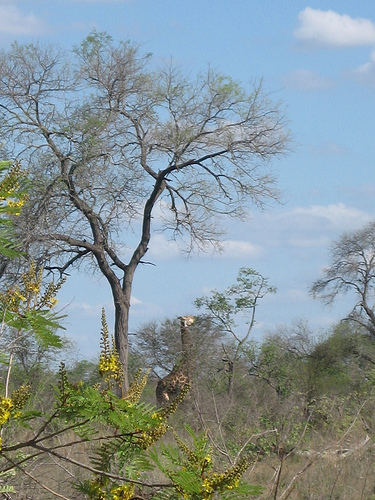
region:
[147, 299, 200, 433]
the giraffe in the field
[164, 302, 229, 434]
the giraffe in the field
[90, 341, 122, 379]
the flowers are yellow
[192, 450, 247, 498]
the flowers are yellow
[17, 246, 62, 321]
the flowers are yellow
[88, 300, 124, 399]
the flowers are yellow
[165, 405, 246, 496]
the flowers are yellow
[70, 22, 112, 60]
little bits of green on tree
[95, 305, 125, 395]
tall golden and brown wildflowers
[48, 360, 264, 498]
several green wild plants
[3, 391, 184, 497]
part of dead tree branch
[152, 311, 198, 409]
giraffe partially hidden by trees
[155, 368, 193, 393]
brown spots of giraffe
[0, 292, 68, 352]
part of wild green plant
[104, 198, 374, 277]
white clouds in blue sky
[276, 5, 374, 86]
white and gray clouds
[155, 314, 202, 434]
a giraffe walking through brush and trees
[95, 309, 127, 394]
golden flowers growing on a bush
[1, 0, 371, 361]
a blue sky appearing above the trees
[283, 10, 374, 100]
white clouds in a blue sky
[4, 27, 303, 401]
a tree with no leaves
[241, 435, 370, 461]
a fallen log lying on the ground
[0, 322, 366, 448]
brush growing close to the ground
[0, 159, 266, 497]
a bush with green leaves and yellow flowers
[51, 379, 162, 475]
green leaves on a bush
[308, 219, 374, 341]
part of a tree with no leaves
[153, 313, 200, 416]
a giraffe in the trees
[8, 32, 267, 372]
tall sparse leaved tree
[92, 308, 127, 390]
weed with yellow petals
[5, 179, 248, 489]
small tree with yellow flowered leaves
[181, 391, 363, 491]
brown grass and weeds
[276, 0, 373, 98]
grey and white cloud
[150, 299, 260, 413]
a giraffe eating leaves from a tree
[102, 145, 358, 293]
blue sky with grey and white clouds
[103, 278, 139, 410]
thin tree trunk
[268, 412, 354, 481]
branches of dead bushes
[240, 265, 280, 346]
This is a branch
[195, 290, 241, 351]
This is a branch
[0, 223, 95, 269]
This is a branch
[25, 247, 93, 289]
This is a branch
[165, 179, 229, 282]
This is a branch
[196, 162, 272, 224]
This is a branch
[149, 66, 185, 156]
This is a branch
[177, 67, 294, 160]
This is a branch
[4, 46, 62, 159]
This is a branch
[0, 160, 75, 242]
This is a branch